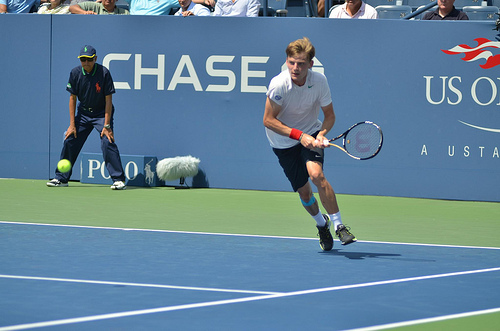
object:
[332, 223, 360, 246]
shoe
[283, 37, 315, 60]
hair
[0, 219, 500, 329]
tennis court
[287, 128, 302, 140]
sweatband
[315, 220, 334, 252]
shoe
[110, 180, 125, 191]
shoe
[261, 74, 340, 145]
white outfit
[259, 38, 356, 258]
player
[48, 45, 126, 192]
linesman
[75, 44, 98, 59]
cap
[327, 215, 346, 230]
white socks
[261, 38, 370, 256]
man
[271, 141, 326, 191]
black shorts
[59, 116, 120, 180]
blue pants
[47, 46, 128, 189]
umpire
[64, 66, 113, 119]
blue shirt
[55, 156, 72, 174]
ball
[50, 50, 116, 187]
player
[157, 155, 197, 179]
microphone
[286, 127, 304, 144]
band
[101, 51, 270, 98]
logo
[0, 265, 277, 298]
lines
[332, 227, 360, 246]
sneaker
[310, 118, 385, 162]
tennis racket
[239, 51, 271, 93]
letters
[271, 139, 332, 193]
shorts